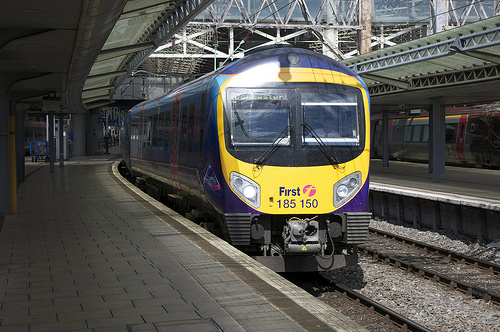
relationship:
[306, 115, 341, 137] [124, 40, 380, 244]
motorman inside train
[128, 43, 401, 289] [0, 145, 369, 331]
train on platform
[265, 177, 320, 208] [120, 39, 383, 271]
id number on train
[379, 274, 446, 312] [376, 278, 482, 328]
gravel under track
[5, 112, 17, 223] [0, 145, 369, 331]
pole on platform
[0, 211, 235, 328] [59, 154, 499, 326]
bricks on ground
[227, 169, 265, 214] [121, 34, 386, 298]
light of train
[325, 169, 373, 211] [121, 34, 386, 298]
light of train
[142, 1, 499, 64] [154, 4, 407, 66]
beams on ceiling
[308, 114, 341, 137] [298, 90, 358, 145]
motorman in window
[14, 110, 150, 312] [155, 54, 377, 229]
platform next to train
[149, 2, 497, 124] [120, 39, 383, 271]
infrastructure above train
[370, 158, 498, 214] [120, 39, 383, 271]
platform beside train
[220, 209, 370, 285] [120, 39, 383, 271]
motor on train